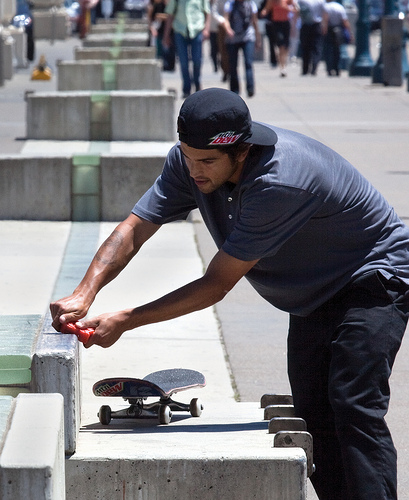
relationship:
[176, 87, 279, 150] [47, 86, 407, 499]
hat of man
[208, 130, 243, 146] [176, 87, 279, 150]
letters are on hat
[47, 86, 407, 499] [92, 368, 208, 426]
man bending over skate board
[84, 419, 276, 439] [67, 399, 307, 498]
shadow on concrete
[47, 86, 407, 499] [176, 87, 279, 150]
man wearing hat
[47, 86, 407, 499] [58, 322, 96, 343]
man holding object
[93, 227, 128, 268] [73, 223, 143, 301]
tattoo on forearm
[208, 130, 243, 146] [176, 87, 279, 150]
company name on hat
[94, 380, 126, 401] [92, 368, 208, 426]
company name on skate board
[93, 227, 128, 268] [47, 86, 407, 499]
tattoo on man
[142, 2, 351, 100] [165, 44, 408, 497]
people are on sidewalk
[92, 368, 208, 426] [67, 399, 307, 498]
skate board on concrete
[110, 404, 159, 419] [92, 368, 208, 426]
axel on skate board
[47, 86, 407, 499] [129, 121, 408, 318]
man wearing shirt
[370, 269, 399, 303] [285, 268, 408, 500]
pocket in pants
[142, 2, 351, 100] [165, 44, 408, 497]
people are walking on sidewalk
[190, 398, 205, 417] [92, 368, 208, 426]
wheel on skate board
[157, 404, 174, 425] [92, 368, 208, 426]
wheel on skate board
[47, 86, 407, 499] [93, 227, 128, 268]
man has tattoo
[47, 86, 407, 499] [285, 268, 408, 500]
man wearing pants